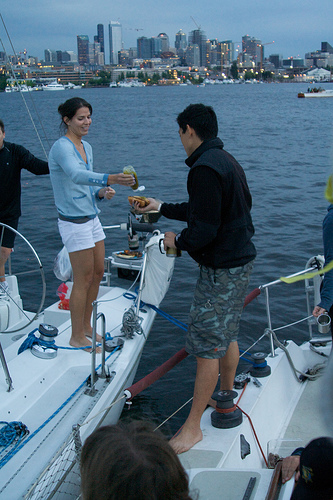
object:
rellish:
[120, 168, 149, 193]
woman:
[41, 101, 135, 348]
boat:
[9, 216, 204, 421]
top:
[47, 141, 105, 218]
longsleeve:
[56, 149, 114, 187]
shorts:
[46, 217, 95, 251]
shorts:
[189, 268, 227, 360]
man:
[141, 101, 273, 450]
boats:
[169, 284, 330, 496]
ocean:
[105, 88, 326, 161]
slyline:
[12, 55, 326, 99]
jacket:
[159, 152, 277, 269]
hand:
[132, 195, 200, 217]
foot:
[165, 420, 207, 450]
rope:
[144, 307, 184, 332]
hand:
[157, 227, 197, 259]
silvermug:
[154, 233, 190, 267]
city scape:
[10, 33, 329, 82]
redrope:
[237, 385, 282, 462]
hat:
[295, 434, 331, 500]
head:
[298, 437, 330, 500]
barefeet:
[65, 309, 123, 364]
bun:
[125, 192, 157, 209]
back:
[183, 101, 226, 136]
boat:
[294, 79, 332, 104]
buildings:
[42, 33, 54, 66]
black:
[4, 149, 32, 229]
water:
[257, 91, 297, 218]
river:
[69, 92, 259, 96]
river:
[158, 88, 244, 101]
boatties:
[210, 381, 247, 431]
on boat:
[117, 258, 331, 500]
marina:
[2, 53, 331, 412]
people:
[2, 120, 45, 280]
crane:
[186, 17, 209, 29]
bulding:
[219, 26, 237, 66]